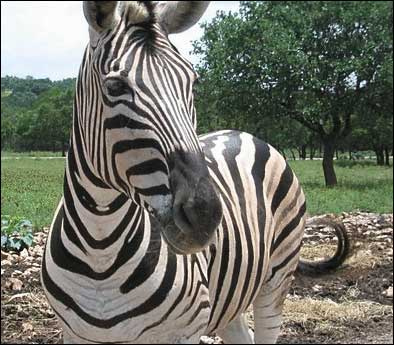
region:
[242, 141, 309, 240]
Grey stripes on a zebras hindquarters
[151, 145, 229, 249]
A black nose on a zebra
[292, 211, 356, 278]
Curling black hair of a zebra's tail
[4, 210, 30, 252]
A green plant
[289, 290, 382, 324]
Dry grass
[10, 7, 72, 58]
A grey sky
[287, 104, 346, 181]
The dark brown trunk of a tree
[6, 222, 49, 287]
Rocks in the dirt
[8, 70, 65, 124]
A hillside in the distance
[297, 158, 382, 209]
Green grass growing amongst the trees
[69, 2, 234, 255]
Zebra's full head in photo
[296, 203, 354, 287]
Zebra curly black tail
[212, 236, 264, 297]
Zebra's black and white stripes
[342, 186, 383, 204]
Green grass behind zebra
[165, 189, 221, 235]
Zebra's black nose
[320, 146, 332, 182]
Tree trunk nearest to zebra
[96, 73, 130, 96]
zebra's right eye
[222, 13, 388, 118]
green tree top closest to zebra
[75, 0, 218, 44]
partial view of zebra's two ears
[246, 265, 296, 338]
zebra's back left leg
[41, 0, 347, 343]
the animal is a zebra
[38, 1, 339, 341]
the zebra has white and black stripes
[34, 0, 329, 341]
the animal is facing the camera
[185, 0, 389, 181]
the tree has several branches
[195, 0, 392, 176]
the tree is green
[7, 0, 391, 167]
there are several trees in the background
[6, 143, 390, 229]
the grass in the picture is green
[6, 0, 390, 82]
the sky at the background is clear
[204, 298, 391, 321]
this is a patch of dry grass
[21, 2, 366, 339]
the zebra is standing on some dirt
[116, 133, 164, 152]
a black zebra strip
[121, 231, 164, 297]
a black zebra strip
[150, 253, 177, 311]
a black zebra strip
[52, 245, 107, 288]
a black zebra strip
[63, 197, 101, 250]
a black zebra strip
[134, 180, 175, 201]
a black zebra strip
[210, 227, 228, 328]
a black zebra strip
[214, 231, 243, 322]
a black zebra strip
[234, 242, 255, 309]
a black zebra strip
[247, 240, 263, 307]
a black zebra strip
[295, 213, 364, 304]
a black, curved tail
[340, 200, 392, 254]
a few rocks in the dirt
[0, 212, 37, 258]
a lone green plant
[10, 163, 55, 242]
an overgrown field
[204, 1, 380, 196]
a beautiful, tall tree in field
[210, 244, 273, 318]
some black and white stripes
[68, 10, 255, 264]
a curious animal face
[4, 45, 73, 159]
a plant covered hill in background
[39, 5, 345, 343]
a lone standing zebra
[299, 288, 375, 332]
some patches of dead grass